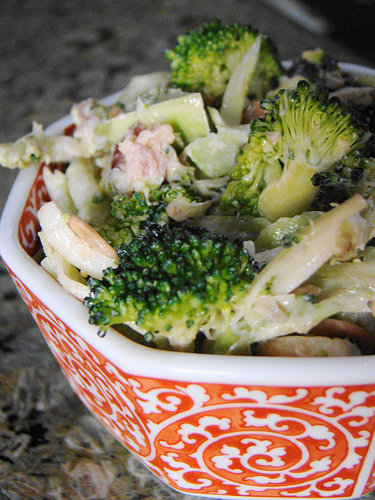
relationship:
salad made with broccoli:
[2, 17, 373, 356] [118, 223, 253, 334]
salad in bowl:
[2, 17, 373, 356] [1, 59, 373, 497]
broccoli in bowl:
[232, 82, 373, 199] [1, 59, 373, 497]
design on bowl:
[68, 355, 346, 464] [0, 187, 326, 472]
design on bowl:
[238, 407, 362, 478] [1, 59, 373, 497]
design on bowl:
[17, 196, 39, 247] [1, 59, 373, 497]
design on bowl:
[149, 384, 375, 500] [1, 59, 373, 497]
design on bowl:
[162, 384, 362, 493] [0, 225, 372, 495]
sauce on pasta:
[0, 47, 375, 355] [226, 198, 370, 326]